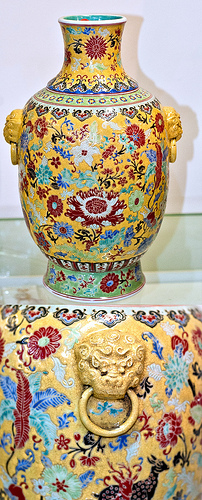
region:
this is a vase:
[0, 12, 185, 311]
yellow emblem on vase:
[65, 327, 157, 441]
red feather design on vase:
[8, 364, 29, 475]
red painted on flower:
[20, 327, 66, 364]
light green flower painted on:
[36, 457, 82, 499]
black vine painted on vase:
[59, 433, 108, 459]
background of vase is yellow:
[62, 26, 122, 92]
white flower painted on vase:
[68, 140, 104, 170]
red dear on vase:
[98, 461, 149, 497]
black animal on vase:
[97, 451, 174, 495]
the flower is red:
[24, 327, 58, 360]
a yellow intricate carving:
[73, 328, 149, 415]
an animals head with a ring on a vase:
[70, 328, 147, 440]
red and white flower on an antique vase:
[63, 186, 128, 232]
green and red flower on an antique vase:
[127, 188, 146, 212]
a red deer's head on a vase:
[105, 456, 143, 499]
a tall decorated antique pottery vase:
[3, 10, 179, 305]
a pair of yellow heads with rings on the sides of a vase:
[3, 105, 183, 167]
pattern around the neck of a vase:
[34, 86, 151, 107]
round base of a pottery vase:
[37, 255, 148, 303]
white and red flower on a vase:
[70, 137, 100, 168]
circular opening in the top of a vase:
[56, 12, 127, 28]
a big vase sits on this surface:
[7, 13, 187, 300]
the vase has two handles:
[2, 106, 182, 165]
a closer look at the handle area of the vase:
[37, 318, 157, 451]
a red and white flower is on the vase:
[69, 182, 131, 231]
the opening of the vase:
[57, 11, 128, 34]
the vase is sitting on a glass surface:
[1, 206, 198, 305]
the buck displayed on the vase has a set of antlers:
[102, 459, 135, 498]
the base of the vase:
[43, 254, 156, 300]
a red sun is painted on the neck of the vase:
[84, 35, 109, 60]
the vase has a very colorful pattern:
[31, 89, 152, 268]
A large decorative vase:
[2, 14, 182, 301]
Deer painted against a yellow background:
[92, 451, 168, 499]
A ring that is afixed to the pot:
[74, 329, 145, 436]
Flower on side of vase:
[153, 411, 182, 448]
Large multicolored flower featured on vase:
[0, 369, 70, 448]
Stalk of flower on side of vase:
[54, 426, 105, 472]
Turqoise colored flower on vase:
[145, 339, 193, 394]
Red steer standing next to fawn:
[103, 457, 141, 498]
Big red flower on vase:
[26, 324, 62, 363]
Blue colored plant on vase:
[107, 429, 130, 453]